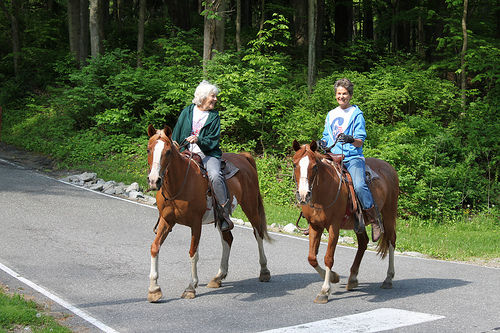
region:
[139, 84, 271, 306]
a lady on a horse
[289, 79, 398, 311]
a woman on a horse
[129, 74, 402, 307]
two riders on horses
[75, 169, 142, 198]
a pile of gray stone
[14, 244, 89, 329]
a white line on the road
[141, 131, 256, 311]
a brown and white horse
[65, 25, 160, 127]
a wooded area behind the trees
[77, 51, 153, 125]
dark green leafy bushes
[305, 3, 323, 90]
a gray tree in the woods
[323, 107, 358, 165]
a light blue hood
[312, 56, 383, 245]
This is a person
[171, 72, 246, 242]
This is a person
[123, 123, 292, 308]
This is a horse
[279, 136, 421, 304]
This is a horse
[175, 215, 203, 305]
Leg of a horse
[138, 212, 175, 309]
Leg of a horse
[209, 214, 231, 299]
Leg of a horse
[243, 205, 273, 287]
Leg of a horse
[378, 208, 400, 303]
Leg of a horse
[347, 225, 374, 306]
Leg of a horse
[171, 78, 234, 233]
White-haired woman riding horse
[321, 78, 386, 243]
Woman in blue riding horse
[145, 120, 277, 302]
Chestnut horse with white blaze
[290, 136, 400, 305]
Chestnut horse crossing paved road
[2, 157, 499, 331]
Paved road in forested area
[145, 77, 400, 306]
Two women riding horses across a road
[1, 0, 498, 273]
Green forested area behind riders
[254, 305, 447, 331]
White marker painted on road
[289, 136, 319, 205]
Chestnut horse head with white blaze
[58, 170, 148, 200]
Pile of gray rocks beside road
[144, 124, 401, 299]
Two white and brown horses.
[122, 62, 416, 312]
Two women riding horses.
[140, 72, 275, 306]
A woman with white hair riding on top of a horse.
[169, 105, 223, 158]
A green zip up jacket.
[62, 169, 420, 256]
Grey rocks along the side of the road.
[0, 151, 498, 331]
The road.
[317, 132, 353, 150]
Black gloves.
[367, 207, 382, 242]
A brown boot.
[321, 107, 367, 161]
A blue jacket.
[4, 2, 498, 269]
Trees and shrubs.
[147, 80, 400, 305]
two women riding horses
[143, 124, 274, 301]
a brown and white horse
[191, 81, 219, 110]
a woman with white hair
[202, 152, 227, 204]
a woman wearing gray pants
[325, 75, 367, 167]
woman holding the reigns of a horse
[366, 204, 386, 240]
a woman wearing boots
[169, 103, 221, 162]
woman wearing a green cardigan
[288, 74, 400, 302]
woman crossing a road on a horse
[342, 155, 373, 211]
woman wearing blue pants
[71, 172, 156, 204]
rocks on the side of a road